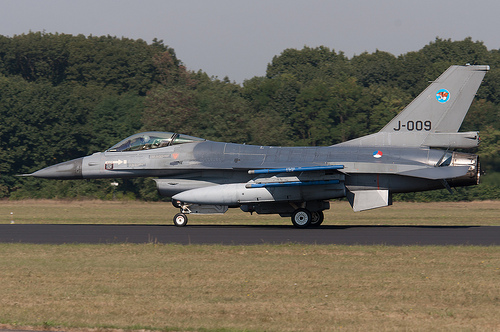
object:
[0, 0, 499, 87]
sky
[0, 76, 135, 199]
trees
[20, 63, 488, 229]
jet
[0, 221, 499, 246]
runway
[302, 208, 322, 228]
wheels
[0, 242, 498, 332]
grass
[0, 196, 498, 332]
ground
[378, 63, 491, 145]
tail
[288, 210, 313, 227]
wheels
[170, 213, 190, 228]
wheel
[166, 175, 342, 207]
missile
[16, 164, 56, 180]
nose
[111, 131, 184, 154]
cockpit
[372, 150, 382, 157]
brand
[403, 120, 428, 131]
number